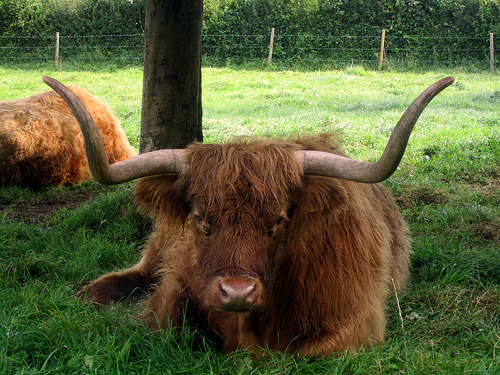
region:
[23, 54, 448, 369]
This is a yak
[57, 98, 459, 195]
the yak has very long horns.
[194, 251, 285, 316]
The yak's snout is brown.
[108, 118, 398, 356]
The brown's fur is brown.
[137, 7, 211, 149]
This is a tree.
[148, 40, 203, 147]
The tree bark is brown.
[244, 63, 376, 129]
This ground is made of grass.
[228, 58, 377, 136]
The grass here is very green.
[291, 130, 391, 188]
The horn's are gray.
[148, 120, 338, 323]
the yak is looking at the camera.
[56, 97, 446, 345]
this is a cow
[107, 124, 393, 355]
the cow is sitted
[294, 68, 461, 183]
this is the horn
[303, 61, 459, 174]
the horn is curved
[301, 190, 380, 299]
the cow is brown in color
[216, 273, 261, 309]
this is the nose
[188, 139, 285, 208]
the cow is fury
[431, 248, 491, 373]
the grass is green in color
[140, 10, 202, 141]
this is a tree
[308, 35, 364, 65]
this is a fence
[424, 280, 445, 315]
part of a ground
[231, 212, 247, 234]
part fo a hea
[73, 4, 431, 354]
brown bull on grass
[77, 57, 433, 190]
bull has long horns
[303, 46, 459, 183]
horns are light brown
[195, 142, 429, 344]
bull has long brown hair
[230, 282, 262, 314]
bull has light brown nose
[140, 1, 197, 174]
brown trunk of tree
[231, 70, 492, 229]
long green grass behind bull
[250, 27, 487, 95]
brown posts on fence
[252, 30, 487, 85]
three wires on fence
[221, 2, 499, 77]
green bushes behind fence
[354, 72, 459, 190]
horn of the animal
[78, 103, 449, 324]
animal with two horns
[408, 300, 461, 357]
green grass next to animal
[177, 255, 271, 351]
nose of the animal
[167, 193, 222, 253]
eye of the animal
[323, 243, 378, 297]
brown fur on animal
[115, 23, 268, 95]
tree behind the animal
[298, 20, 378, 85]
fence behind the animal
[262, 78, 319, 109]
light hitting the grass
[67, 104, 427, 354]
animal looking towards camera